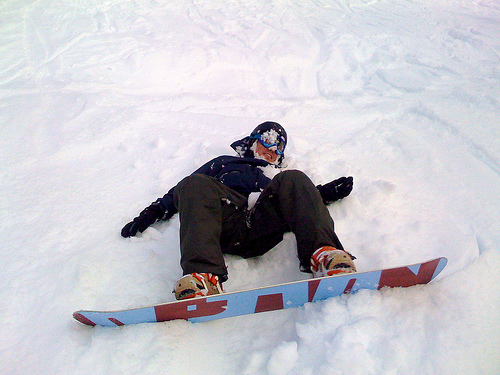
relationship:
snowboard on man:
[71, 256, 447, 326] [119, 114, 359, 299]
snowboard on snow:
[74, 255, 446, 332] [1, 0, 498, 372]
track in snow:
[380, 102, 499, 249] [1, 0, 498, 372]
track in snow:
[4, 75, 397, 115] [1, 0, 498, 372]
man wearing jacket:
[119, 121, 357, 302] [158, 157, 286, 219]